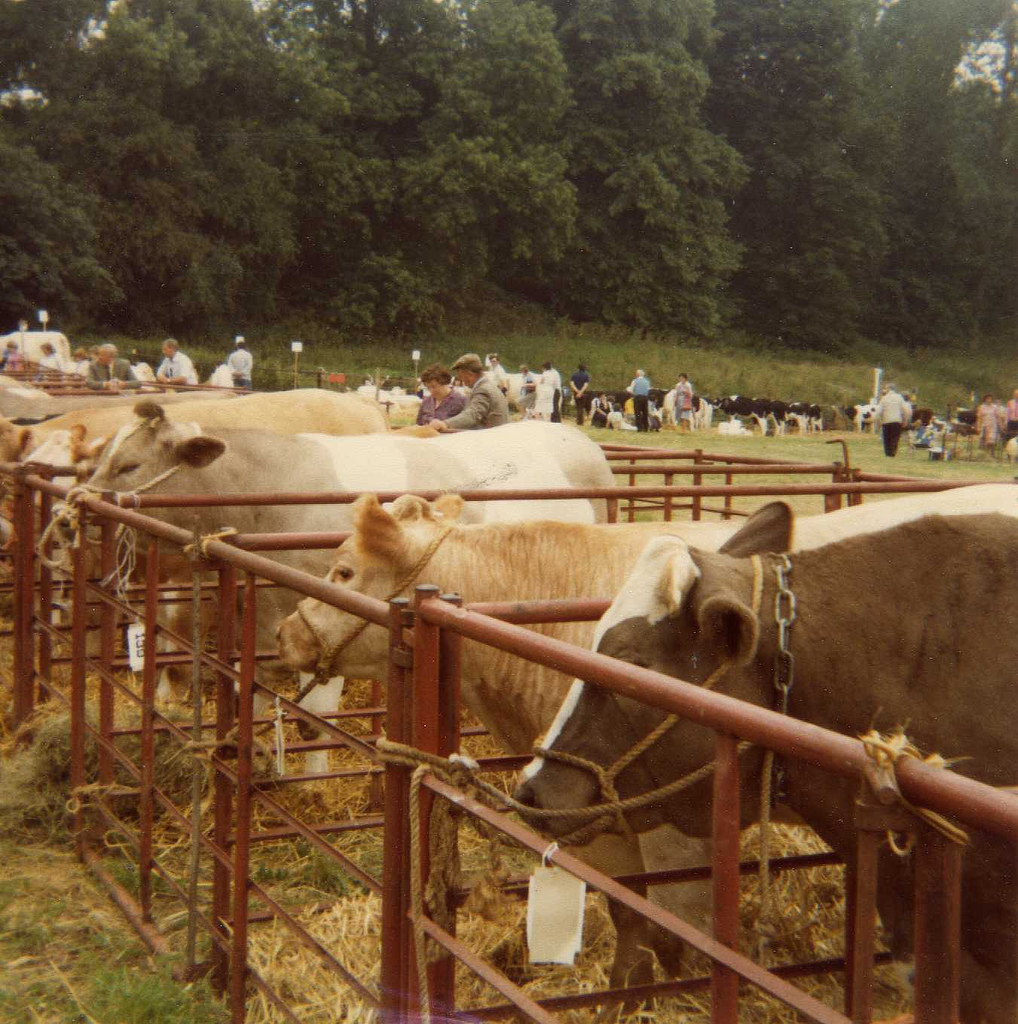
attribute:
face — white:
[502, 569, 735, 813]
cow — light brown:
[257, 517, 823, 990]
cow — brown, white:
[65, 420, 627, 793]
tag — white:
[513, 854, 601, 994]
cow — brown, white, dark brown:
[516, 487, 1015, 1020]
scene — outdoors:
[7, 5, 1013, 1021]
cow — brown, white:
[469, 507, 1009, 1017]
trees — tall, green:
[1, 3, 1015, 354]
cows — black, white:
[622, 357, 849, 451]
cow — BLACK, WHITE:
[745, 390, 791, 441]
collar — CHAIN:
[758, 553, 811, 810]